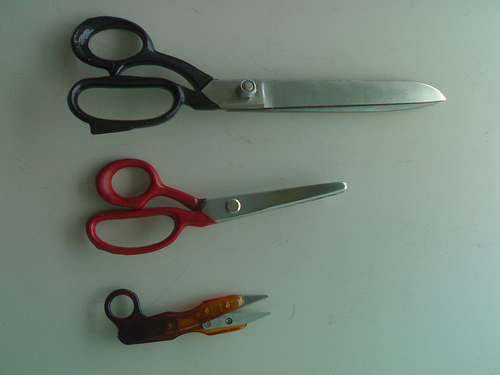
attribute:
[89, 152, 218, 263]
handle — red 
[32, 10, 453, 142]
scissors — silver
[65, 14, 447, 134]
scissor — large, small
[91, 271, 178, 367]
handle — dark brown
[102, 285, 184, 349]
handle — brown 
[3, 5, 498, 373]
table — white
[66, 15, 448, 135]
scissors — black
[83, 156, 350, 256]
scissors — red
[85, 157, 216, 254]
handle — red 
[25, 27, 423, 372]
scissors — three pair, silver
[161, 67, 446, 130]
scissors — silver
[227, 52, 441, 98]
blades — silver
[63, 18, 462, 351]
scissors — brown, three pairs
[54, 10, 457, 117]
scissors — large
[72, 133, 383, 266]
scissors — silver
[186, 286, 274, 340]
blades — short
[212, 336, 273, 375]
hair — curved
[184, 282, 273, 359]
blade — small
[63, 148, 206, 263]
handled — red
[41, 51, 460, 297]
surface — white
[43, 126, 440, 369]
surface — flat and white